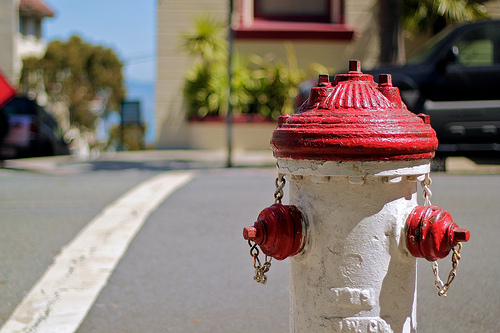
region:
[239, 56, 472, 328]
red and white fire hydrant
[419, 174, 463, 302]
chain links dangling from hydrant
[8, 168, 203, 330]
white stripe painted on road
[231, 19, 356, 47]
red window sill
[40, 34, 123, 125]
green leaves on tree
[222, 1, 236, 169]
tall grey metal street sign post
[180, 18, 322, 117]
bushes planted in flower bed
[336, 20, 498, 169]
black sport utility vehicle parked on street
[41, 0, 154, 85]
cloudless blue sky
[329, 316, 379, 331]
letters J.W.C. engraved in hydrant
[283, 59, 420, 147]
Top of fire hydrant is red.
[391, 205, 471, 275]
Red nozzle on fire hydrant.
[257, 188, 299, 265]
Red nozzle on fire hydrant.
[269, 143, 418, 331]
White fire hydrant.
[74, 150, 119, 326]
White line across the street.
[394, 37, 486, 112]
Black vehicle on road.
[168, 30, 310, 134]
Green plants near building.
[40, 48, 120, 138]
Green leaves on tree in distance.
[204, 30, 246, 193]
Pole on side of street.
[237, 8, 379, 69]
Red window frame on building.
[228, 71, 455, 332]
old fire hydrant on street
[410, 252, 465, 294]
metal chain hanging down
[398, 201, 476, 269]
red side panel of hydrant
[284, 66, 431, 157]
red top of hydrant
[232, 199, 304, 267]
red side panel on hydrant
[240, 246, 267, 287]
metal chain attached to red panel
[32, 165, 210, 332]
white line painted on street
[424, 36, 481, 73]
side view mirror on car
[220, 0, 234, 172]
silver street pole on street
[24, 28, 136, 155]
tree by side of street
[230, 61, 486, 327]
the hydrant is red and white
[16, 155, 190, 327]
a thick white line on the street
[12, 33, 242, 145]
the background is blurry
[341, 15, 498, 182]
a car is parked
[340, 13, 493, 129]
the car is black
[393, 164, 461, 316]
a chain on the hydrant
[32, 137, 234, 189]
shadow on the ground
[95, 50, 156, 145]
water in the distance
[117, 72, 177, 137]
the water is blue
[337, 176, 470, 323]
the sun is on the hydrant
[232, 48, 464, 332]
A red and white fire hydrant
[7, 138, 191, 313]
a white line in the road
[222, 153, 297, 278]
A chain on a fire hydrant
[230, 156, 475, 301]
Two chains on a fire hydrant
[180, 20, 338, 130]
Plants behind the fire hydrant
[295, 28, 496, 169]
A car parked in the street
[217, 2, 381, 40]
A window on a building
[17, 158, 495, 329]
A street behind the fire hydrant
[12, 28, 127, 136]
Trees in the distance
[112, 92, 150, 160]
A sign in the distance